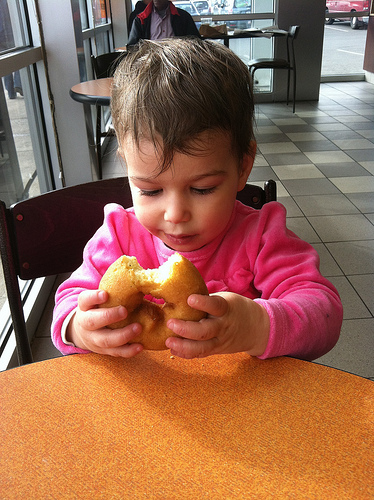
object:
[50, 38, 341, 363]
girl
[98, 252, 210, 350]
donut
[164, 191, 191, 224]
nose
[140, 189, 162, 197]
eyes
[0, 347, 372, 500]
table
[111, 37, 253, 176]
hair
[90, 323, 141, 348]
fingers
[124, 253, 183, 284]
bite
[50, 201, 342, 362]
shirt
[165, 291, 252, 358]
hand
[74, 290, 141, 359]
hand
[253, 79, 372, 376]
tile floor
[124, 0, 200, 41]
man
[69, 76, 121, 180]
table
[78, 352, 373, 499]
shadow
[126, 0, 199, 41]
jacket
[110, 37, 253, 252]
head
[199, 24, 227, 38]
paper bag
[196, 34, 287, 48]
table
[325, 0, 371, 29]
truck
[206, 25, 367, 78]
parking lot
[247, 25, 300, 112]
chair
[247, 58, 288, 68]
cushion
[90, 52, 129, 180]
chair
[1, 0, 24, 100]
pedestrian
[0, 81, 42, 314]
sidewalk